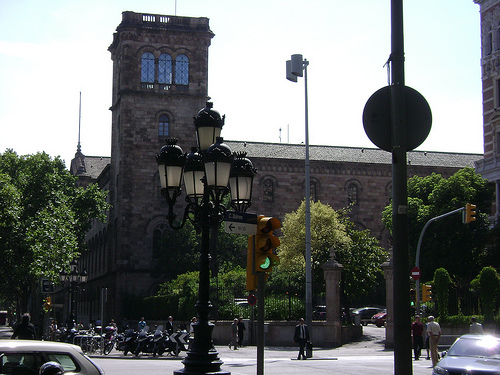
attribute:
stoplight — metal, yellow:
[241, 212, 282, 301]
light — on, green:
[257, 254, 273, 273]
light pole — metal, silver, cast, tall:
[285, 52, 315, 359]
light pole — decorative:
[149, 99, 255, 375]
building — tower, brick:
[104, 7, 217, 340]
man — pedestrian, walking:
[290, 316, 312, 361]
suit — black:
[291, 324, 311, 358]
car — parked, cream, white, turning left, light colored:
[1, 338, 104, 374]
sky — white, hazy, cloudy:
[1, 1, 482, 170]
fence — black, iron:
[214, 278, 324, 320]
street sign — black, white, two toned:
[223, 208, 258, 239]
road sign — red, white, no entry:
[410, 266, 421, 283]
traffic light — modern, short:
[243, 213, 282, 298]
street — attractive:
[41, 339, 473, 374]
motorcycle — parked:
[152, 322, 181, 358]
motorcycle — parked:
[131, 325, 155, 356]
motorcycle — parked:
[119, 330, 139, 359]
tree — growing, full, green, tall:
[1, 148, 110, 344]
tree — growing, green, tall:
[0, 171, 17, 332]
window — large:
[140, 47, 158, 87]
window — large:
[156, 49, 173, 87]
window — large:
[174, 51, 193, 90]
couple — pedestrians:
[227, 313, 247, 349]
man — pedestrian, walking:
[425, 315, 442, 371]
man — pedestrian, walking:
[410, 312, 426, 363]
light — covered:
[290, 52, 306, 80]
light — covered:
[284, 58, 300, 83]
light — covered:
[201, 135, 233, 209]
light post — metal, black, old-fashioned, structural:
[182, 213, 221, 369]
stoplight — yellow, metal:
[419, 282, 434, 305]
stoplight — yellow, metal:
[463, 202, 477, 228]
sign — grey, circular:
[359, 83, 437, 156]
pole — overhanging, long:
[410, 202, 463, 327]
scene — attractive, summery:
[3, 5, 496, 372]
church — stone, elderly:
[43, 7, 485, 335]